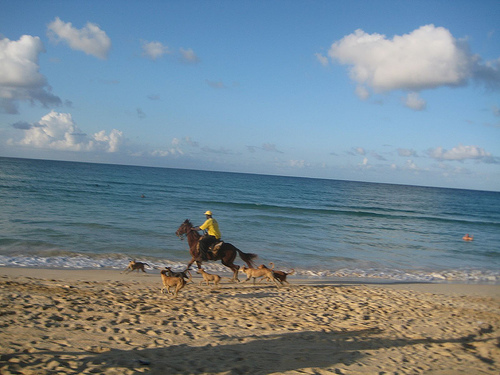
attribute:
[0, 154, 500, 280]
water — blue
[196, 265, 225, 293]
dog — running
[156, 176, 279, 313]
horse — brown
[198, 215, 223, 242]
shirt — yellow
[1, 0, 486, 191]
skies — partly cloudy, blue